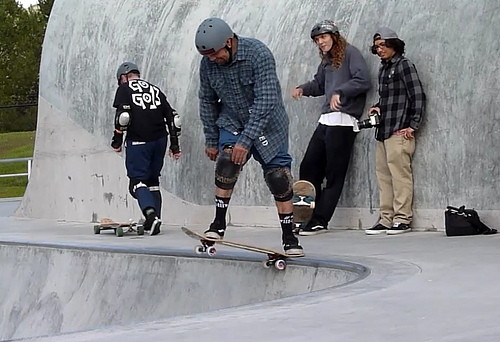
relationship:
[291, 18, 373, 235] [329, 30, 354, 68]
man has hair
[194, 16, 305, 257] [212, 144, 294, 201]
man wearing knee pads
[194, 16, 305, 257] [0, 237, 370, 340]
man at edge of ramp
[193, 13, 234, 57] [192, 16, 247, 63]
gray helmet on head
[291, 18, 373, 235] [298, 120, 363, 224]
man wearing pants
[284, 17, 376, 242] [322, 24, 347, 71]
man has hair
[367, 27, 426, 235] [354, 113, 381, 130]
man holding camera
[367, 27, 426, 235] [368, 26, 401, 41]
man wearing cap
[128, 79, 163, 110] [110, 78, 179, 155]
letter on shirt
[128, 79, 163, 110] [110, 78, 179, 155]
letter on back of shirt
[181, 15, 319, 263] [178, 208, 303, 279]
man on skateboard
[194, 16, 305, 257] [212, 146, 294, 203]
man wearing pads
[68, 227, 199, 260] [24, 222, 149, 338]
edge of ramp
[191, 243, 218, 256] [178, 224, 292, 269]
wheels under board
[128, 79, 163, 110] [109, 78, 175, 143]
letter on back of shirt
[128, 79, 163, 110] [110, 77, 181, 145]
letter on shirt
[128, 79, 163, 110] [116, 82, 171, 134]
letter on shirt.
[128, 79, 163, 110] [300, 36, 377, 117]
letter on shirt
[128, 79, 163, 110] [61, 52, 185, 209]
letter on shirt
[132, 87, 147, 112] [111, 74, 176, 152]
letter on shirt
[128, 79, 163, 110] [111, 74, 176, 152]
letter on shirt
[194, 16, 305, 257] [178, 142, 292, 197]
man wearing kneepads